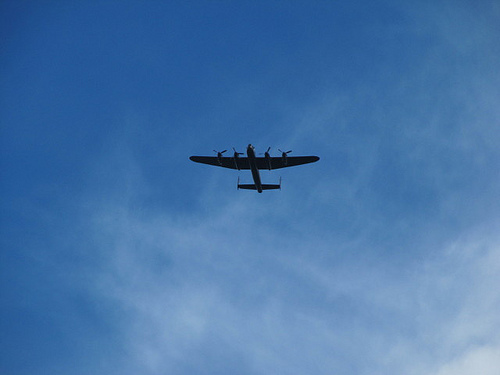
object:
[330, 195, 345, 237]
ground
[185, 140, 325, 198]
aircraft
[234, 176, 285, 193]
back tail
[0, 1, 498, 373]
sky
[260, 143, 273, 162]
propeller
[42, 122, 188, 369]
clouds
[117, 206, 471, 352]
clouds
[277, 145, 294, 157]
propeller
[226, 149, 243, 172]
engine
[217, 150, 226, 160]
engine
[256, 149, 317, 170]
wing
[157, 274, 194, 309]
cloud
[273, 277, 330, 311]
cloud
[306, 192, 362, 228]
cloud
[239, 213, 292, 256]
cloud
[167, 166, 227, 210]
cloud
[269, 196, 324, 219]
cloud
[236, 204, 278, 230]
cloud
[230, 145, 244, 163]
propeller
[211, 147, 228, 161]
propeller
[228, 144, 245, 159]
propeller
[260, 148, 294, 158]
engine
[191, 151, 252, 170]
wing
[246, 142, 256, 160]
nose